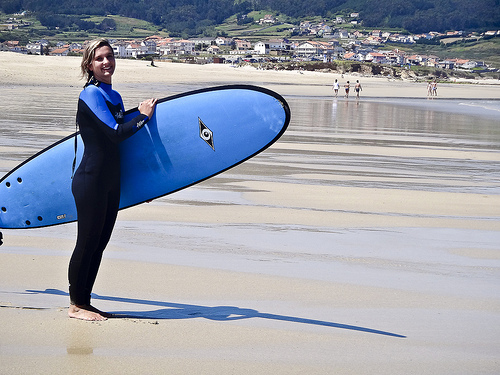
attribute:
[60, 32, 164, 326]
lady — blonde, barefeet, happy, smiling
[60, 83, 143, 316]
wet suit — black, blue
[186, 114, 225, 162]
logo — black, white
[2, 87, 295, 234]
board — black, blue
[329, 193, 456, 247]
sand — wet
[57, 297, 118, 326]
feet — bare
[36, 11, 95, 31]
tree — green